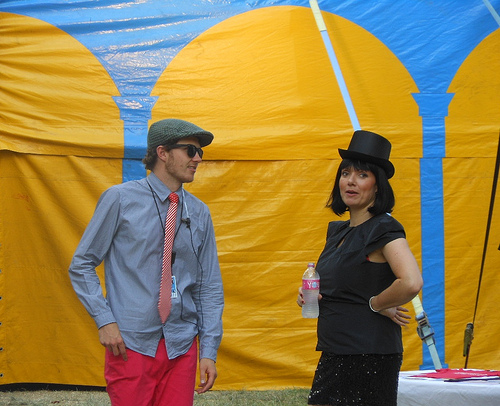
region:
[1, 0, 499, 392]
yellow and blue plastic tent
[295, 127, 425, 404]
woman holding her hand on her hip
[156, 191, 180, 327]
red and white patterned necktie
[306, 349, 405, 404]
black sequined skirt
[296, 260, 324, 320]
hand holding a plastic water bottle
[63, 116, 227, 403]
man wearing dark sunglasses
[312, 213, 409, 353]
black cap sleeved blouse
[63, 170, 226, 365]
blue long sleeved shirt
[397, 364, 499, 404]
red paper on a white draped surface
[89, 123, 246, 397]
this is a person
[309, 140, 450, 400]
this is a person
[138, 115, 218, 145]
this is a hat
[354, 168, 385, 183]
an eye of a person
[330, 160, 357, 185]
an eye of a person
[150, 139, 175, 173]
an ear of a person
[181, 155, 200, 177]
an eye of a person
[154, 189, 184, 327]
Red tie with stripes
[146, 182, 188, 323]
Red tie with stripes next to an ID badge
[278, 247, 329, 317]
Bottle of water with cap off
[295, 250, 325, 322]
Hand holding a water bottle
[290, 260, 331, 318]
Hand with red nail polish holding a water bottle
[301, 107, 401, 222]
A lady wearing a black hat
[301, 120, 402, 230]
A lady with black hair wearing a black hat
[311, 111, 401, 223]
A lady with a bob haircut wearing a black hat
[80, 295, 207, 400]
Red pants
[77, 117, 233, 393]
a man in a red tie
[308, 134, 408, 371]
a woman wearing a black shirt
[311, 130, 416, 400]
a woman wearing a black hat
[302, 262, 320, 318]
a water bottle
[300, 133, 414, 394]
a woman holding a water bottle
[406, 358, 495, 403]
a white table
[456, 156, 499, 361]
a black strap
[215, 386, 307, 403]
grass behind the people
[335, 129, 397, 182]
a black hat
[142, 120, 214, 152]
a gray hat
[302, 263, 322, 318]
a clear water bottle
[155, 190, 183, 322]
a long red and white tie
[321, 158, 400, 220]
a woman's short black hair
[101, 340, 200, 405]
part of a man's red pants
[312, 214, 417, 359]
a woman's black shirt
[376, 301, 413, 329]
the hand of a woman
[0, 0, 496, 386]
a large blue and yellow tent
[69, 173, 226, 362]
a man's long sleeve gray shirt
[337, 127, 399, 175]
the woman is wearing a hat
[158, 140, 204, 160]
the man is wearing sunglasses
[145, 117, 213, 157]
the man is wearing a cap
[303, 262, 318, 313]
the bottle is made of plastic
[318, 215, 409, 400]
the dress is black in color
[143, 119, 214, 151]
hat worn by human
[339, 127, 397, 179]
hat worn by human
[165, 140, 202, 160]
glasses worn by human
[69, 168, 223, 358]
shirt worn by human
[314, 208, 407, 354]
shirt worn by human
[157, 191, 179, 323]
tie worn by human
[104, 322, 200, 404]
pants worn by human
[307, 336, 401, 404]
skirt worn by human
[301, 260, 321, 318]
woman holds bottle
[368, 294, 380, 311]
watch worn by human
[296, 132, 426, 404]
lady in a black shirt and skirt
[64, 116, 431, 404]
guy looking at a lady who is holding water